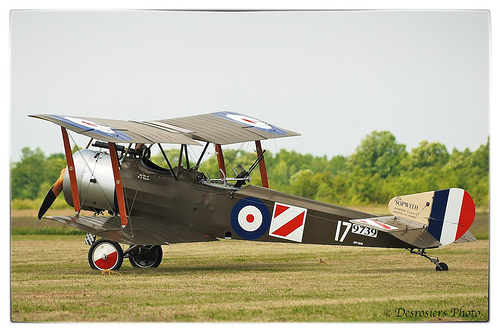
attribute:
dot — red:
[244, 212, 254, 222]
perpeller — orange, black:
[35, 163, 67, 217]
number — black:
[351, 221, 378, 238]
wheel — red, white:
[88, 238, 123, 275]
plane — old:
[20, 92, 468, 284]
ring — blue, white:
[232, 199, 272, 241]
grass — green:
[180, 258, 495, 318]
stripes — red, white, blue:
[430, 185, 477, 248]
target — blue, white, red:
[224, 193, 273, 263]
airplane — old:
[33, 78, 442, 258]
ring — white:
[239, 205, 263, 231]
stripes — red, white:
[392, 178, 487, 240]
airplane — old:
[27, 93, 479, 278]